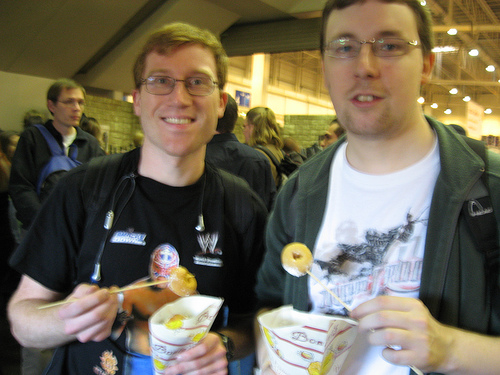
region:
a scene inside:
[6, 11, 484, 372]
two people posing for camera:
[2, 9, 499, 373]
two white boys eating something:
[1, 0, 494, 371]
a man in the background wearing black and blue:
[2, 59, 113, 264]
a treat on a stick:
[253, 222, 428, 373]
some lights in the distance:
[385, 1, 499, 128]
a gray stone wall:
[69, 71, 173, 201]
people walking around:
[2, 53, 473, 267]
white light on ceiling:
[447, 25, 457, 40]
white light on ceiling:
[466, 44, 480, 57]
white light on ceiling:
[485, 60, 495, 74]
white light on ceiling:
[447, 82, 458, 95]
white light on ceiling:
[461, 94, 473, 104]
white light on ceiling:
[483, 108, 490, 115]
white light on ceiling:
[416, 94, 426, 104]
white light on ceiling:
[428, 100, 439, 110]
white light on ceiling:
[443, 108, 452, 114]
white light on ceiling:
[421, 1, 429, 6]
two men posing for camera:
[20, 23, 491, 365]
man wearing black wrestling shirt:
[5, 30, 259, 370]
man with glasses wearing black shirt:
[15, 20, 271, 362]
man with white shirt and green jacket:
[265, 0, 493, 373]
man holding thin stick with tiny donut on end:
[271, 10, 498, 348]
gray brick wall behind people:
[82, 97, 144, 148]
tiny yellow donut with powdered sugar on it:
[165, 263, 197, 303]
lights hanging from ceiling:
[415, 9, 495, 114]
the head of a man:
[41, 76, 91, 133]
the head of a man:
[121, 23, 243, 160]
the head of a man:
[312, 3, 442, 147]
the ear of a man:
[43, 94, 58, 117]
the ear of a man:
[124, 84, 144, 120]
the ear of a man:
[212, 89, 229, 124]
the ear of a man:
[420, 42, 439, 85]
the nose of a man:
[164, 81, 195, 112]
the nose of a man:
[349, 42, 381, 84]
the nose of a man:
[69, 99, 84, 114]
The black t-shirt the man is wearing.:
[100, 180, 221, 300]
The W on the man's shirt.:
[197, 230, 218, 252]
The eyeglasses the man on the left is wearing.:
[128, 72, 224, 97]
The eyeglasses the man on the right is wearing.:
[326, 35, 418, 59]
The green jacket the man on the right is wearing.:
[270, 124, 497, 319]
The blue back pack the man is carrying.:
[31, 123, 80, 179]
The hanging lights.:
[419, 3, 498, 129]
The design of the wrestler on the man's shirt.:
[103, 251, 205, 373]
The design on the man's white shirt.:
[315, 200, 418, 307]